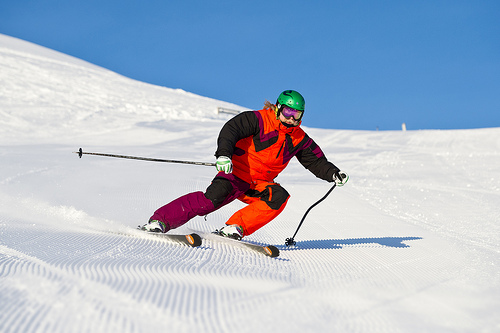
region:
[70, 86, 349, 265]
person skiing down a slope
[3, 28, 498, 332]
snow covered ski slope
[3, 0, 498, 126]
clear blue sky in top of photo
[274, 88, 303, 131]
green helmet on head of skier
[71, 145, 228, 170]
ski pole in right hand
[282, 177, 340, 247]
ski pole in left hand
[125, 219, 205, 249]
ski on right foot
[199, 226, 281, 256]
ski on left foot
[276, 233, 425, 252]
shadow of skier on ground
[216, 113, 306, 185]
upper torso of skier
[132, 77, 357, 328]
man going down a hill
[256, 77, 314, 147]
man wears a green helmet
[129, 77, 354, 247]
man wears a winter suit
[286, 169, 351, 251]
a pole on left hand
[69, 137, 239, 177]
a pole on right hand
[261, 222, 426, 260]
a shadow cast on the snow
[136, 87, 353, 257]
winter suit is color orange, black and purple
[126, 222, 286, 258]
skis are color silver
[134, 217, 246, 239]
a pair of white shoes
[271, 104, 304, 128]
man wearing goggles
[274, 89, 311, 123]
green helmet on skier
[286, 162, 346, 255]
crooked ski pole in skier's hand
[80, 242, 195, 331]
grooves in the snow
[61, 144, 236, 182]
ski pole extended out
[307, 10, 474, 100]
clear blue sky overhead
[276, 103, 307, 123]
reflective goggles on skier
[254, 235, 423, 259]
skier's shadow on ground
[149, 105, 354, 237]
orange, purple, and black ski suit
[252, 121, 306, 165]
chevrons on front of jacket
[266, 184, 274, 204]
zipper on front of ski pants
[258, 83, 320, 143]
Person wearing green helmet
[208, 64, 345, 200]
Person wearing red and black ski coat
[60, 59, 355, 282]
Person skiing downhill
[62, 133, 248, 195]
Ski pole in right hand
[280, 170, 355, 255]
Ski pole in left hand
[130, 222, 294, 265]
Person wearing black skis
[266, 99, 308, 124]
Person is wearing goggles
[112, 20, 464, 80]
Clear blue sunny sky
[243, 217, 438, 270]
Shadow of skier on the snow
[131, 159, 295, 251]
Person is wearing red and black ski pants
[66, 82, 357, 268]
A skier holding two ski poles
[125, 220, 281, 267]
Pair of black skis with yellow ovals on the bottom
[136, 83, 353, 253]
A skier wearing a green helmet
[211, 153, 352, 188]
White gloves with green designs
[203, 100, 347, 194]
An orange ski jacket with black sleeves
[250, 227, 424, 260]
A shadow of a skier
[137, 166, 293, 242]
Orange ski pants with black design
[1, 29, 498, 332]
A snowy ski slope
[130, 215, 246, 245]
White pair of ski boots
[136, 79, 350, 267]
Skier skiing down a hill